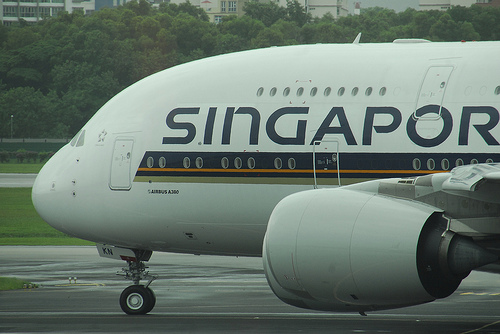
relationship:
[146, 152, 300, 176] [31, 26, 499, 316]
windows on side of plane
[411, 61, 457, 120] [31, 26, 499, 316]
door on side of plane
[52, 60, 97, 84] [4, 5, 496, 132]
leaves on many trees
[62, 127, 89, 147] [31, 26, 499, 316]
front windows of plane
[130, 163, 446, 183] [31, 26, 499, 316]
lines on side of plane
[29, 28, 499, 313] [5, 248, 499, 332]
airplane on ground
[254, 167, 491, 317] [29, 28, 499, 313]
engine on airplane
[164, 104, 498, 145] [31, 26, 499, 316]
singapor on side of plane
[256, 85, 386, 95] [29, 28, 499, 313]
windows on airplane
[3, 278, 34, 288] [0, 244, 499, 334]
grass near ground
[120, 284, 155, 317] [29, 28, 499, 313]
wheel of airplane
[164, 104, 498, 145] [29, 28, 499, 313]
singapor on airplane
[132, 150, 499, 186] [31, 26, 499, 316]
stripe on side of plane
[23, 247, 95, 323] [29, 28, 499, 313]
runway by airplane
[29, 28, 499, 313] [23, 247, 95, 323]
airplane on runway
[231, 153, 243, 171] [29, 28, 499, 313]
window by airplane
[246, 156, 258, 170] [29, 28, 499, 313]
window by airplane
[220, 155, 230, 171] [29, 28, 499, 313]
window by airplane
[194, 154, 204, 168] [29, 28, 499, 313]
window by airplane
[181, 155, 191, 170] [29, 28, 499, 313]
window by airplane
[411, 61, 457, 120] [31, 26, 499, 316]
door by plane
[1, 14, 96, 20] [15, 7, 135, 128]
buildings by forest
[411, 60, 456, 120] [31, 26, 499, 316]
door on plane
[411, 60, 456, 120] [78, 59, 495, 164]
door on side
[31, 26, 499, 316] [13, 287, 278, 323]
plane on runway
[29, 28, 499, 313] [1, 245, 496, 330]
airplane on runway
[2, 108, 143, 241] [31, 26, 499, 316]
nose on plane